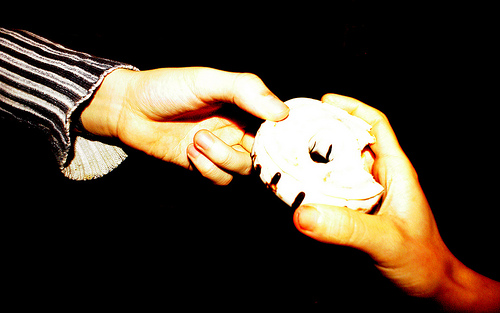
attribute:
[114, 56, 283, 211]
hand — the right , the  left, holding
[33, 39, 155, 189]
wrist — white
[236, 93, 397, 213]
donut — white, small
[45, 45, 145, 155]
sleeve — black